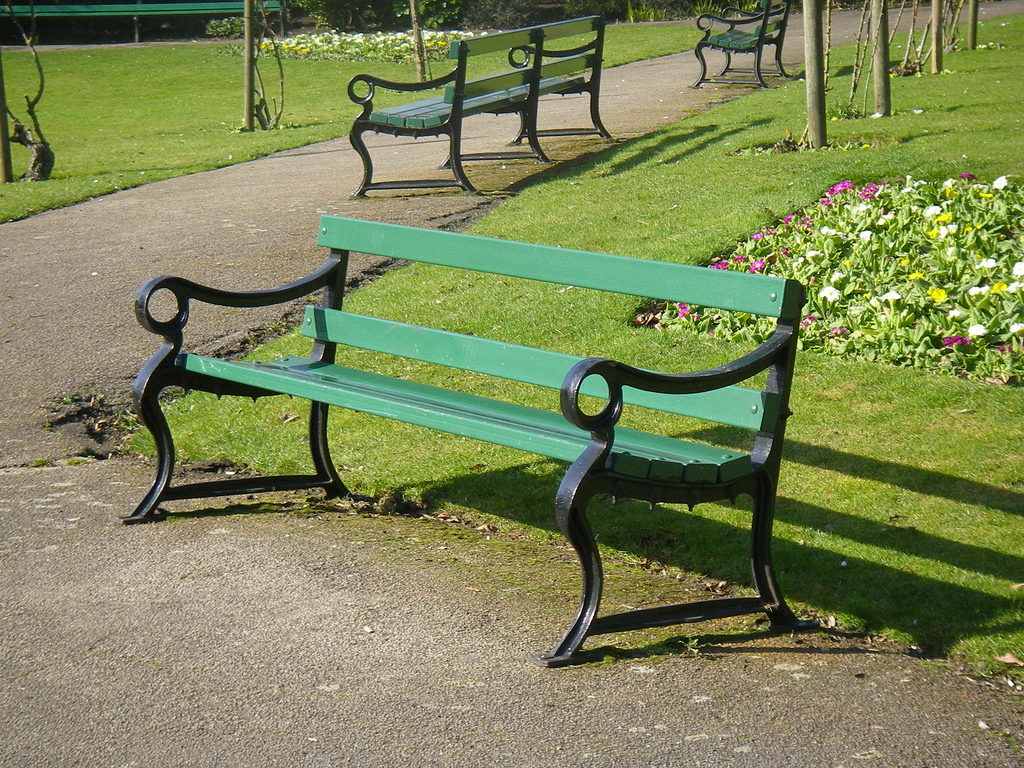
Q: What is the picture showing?
A: It is showing a sidewalk.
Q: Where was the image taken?
A: It was taken at the sidewalk.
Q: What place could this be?
A: It is a sidewalk.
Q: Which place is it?
A: It is a sidewalk.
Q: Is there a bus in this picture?
A: No, there are no buses.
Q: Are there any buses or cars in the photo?
A: No, there are no buses or cars.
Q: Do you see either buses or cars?
A: No, there are no buses or cars.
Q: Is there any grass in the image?
A: Yes, there is grass.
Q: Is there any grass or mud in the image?
A: Yes, there is grass.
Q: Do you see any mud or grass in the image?
A: Yes, there is grass.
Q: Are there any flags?
A: No, there are no flags.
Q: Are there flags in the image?
A: No, there are no flags.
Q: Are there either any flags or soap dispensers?
A: No, there are no flags or soap dispensers.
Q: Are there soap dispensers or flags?
A: No, there are no flags or soap dispensers.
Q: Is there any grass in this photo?
A: Yes, there is grass.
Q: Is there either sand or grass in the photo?
A: Yes, there is grass.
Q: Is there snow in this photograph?
A: No, there is no snow.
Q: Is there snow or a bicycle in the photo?
A: No, there are no snow or bicycles.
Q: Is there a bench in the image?
A: Yes, there is a bench.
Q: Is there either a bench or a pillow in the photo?
A: Yes, there is a bench.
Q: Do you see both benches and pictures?
A: No, there is a bench but no pictures.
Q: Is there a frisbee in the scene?
A: No, there are no frisbees.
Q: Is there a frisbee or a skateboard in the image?
A: No, there are no frisbees or skateboards.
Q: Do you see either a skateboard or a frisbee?
A: No, there are no frisbees or skateboards.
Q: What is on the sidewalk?
A: The bench is on the sidewalk.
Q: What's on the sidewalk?
A: The bench is on the sidewalk.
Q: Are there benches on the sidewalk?
A: Yes, there is a bench on the sidewalk.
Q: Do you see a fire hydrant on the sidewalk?
A: No, there is a bench on the sidewalk.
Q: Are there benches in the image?
A: Yes, there is a bench.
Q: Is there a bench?
A: Yes, there is a bench.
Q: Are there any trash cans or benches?
A: Yes, there is a bench.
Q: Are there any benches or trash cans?
A: Yes, there is a bench.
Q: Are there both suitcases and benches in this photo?
A: No, there is a bench but no suitcases.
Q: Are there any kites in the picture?
A: No, there are no kites.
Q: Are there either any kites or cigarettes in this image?
A: No, there are no kites or cigarettes.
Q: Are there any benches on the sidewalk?
A: Yes, there is a bench on the sidewalk.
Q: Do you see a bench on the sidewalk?
A: Yes, there is a bench on the sidewalk.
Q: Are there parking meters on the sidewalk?
A: No, there is a bench on the sidewalk.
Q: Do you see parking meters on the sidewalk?
A: No, there is a bench on the sidewalk.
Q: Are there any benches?
A: Yes, there is a bench.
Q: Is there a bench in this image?
A: Yes, there is a bench.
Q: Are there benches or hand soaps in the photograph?
A: Yes, there is a bench.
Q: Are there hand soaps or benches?
A: Yes, there is a bench.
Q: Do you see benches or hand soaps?
A: Yes, there is a bench.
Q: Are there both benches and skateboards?
A: No, there is a bench but no skateboards.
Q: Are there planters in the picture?
A: No, there are no planters.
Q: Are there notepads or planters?
A: No, there are no planters or notepads.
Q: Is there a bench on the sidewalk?
A: Yes, there is a bench on the sidewalk.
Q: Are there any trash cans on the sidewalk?
A: No, there is a bench on the sidewalk.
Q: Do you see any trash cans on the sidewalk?
A: No, there is a bench on the sidewalk.